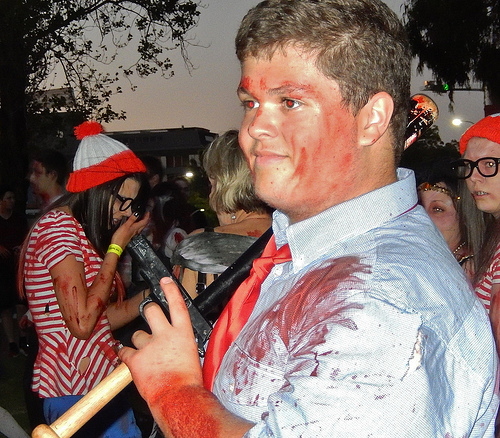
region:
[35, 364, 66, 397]
red stripe on shirt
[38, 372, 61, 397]
red stripe on shirt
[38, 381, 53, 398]
red stripe on shirt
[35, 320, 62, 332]
red stripe on shirt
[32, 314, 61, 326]
red stripe on shirt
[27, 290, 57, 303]
red stripe on shirt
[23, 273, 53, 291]
red stripe on shirt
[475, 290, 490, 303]
red stripe on shirt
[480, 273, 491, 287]
red stripe on shirt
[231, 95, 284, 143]
nose of the person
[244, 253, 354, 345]
fake blood on shirt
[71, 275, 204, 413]
hand of the person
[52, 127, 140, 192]
hat on girl's head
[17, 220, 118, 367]
red and white shirt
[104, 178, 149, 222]
glasses on girl's face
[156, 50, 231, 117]
sky above the land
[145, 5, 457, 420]
man with fake blood on his face and arms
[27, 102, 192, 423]
woman wearing red and white stripe shirt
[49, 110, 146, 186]
red and white hat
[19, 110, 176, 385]
woman with fake blood on her arms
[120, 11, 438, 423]
man holding toy gun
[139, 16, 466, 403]
man holding a baseball bat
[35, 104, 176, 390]
woman wearing eyeglasses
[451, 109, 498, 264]
woman wearing fake teeth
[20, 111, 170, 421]
a girl dressed as wheres waldo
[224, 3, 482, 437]
a fat kid in a white shirt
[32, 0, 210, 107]
tree branches in the sunset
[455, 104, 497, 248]
a girl in a orange beanie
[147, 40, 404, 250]
A boy with blood all over his face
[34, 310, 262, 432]
A arm with blood all over it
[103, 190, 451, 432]
A boys shirt with blood all over it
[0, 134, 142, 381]
A girl with a red and white shirt with blood on her arms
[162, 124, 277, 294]
A woman with blonde hair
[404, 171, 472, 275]
A girl with a gold band around her head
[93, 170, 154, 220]
A girl with black glasses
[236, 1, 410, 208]
man with red paint on face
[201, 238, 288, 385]
red tie with loose knot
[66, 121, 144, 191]
red and white cap with pom pom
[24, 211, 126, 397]
red and white striped shirt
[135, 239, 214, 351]
finger in black hand gun